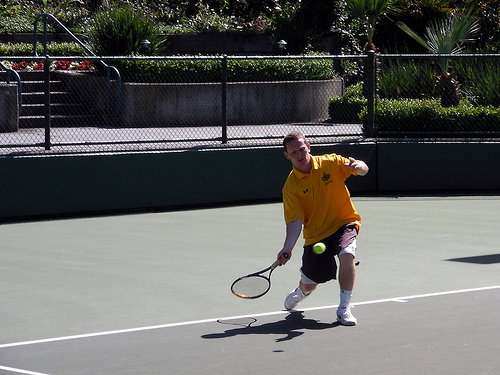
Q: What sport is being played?
A: Tennis.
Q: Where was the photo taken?
A: At a tennis court.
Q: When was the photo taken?
A: During the day.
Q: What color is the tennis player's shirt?
A: Bright yellow-gold.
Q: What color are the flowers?
A: Red and white.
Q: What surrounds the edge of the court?
A: A chain link fence.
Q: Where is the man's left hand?
A: In the air parallel to his shoulder.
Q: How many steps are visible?
A: Five.